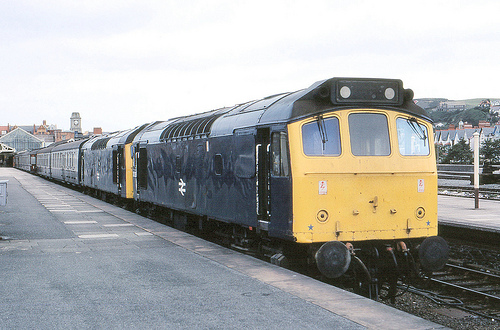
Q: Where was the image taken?
A: It was taken at the train station.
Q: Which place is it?
A: It is a train station.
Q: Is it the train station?
A: Yes, it is the train station.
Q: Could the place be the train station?
A: Yes, it is the train station.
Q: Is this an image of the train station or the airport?
A: It is showing the train station.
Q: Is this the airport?
A: No, it is the train station.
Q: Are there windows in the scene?
A: Yes, there are windows.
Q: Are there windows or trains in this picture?
A: Yes, there are windows.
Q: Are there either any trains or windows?
A: Yes, there are windows.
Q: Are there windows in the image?
A: Yes, there are windows.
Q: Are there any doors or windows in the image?
A: Yes, there are windows.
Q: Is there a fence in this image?
A: No, there are no fences.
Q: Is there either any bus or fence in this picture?
A: No, there are no fences or buses.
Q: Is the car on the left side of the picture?
A: Yes, the car is on the left of the image.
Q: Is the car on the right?
A: No, the car is on the left of the image.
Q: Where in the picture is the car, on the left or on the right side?
A: The car is on the left of the image.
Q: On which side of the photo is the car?
A: The car is on the left of the image.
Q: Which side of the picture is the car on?
A: The car is on the left of the image.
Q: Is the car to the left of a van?
A: No, the car is to the left of a train car.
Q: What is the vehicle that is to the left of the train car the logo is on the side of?
A: The vehicle is a car.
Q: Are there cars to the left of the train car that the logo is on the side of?
A: Yes, there is a car to the left of the train car.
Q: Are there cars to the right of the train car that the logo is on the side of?
A: No, the car is to the left of the train car.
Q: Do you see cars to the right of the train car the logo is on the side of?
A: No, the car is to the left of the train car.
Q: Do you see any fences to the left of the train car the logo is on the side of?
A: No, there is a car to the left of the train car.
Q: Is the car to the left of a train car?
A: Yes, the car is to the left of a train car.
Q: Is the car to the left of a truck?
A: No, the car is to the left of a train car.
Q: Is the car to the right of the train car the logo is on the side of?
A: No, the car is to the left of the train car.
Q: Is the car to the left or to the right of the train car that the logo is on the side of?
A: The car is to the left of the train car.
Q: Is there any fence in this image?
A: No, there are no fences.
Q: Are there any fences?
A: No, there are no fences.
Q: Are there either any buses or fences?
A: No, there are no fences or buses.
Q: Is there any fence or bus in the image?
A: No, there are no fences or buses.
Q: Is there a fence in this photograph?
A: No, there are no fences.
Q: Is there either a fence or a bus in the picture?
A: No, there are no fences or buses.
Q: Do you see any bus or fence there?
A: No, there are no fences or buses.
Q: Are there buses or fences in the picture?
A: No, there are no fences or buses.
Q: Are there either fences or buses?
A: No, there are no fences or buses.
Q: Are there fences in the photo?
A: No, there are no fences.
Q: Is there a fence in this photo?
A: No, there are no fences.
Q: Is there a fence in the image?
A: No, there are no fences.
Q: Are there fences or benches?
A: No, there are no fences or benches.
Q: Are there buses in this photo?
A: No, there are no buses.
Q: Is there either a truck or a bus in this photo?
A: No, there are no buses or trucks.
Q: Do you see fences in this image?
A: No, there are no fences.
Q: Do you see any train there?
A: Yes, there is a train.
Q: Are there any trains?
A: Yes, there is a train.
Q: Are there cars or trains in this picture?
A: Yes, there is a train.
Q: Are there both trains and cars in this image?
A: Yes, there are both a train and a car.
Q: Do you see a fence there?
A: No, there are no fences.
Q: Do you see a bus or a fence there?
A: No, there are no fences or buses.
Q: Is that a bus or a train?
A: That is a train.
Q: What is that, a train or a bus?
A: That is a train.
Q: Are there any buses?
A: No, there are no buses.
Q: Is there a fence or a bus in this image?
A: No, there are no buses or fences.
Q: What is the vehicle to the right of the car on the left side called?
A: The vehicle is a train car.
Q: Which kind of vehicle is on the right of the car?
A: The vehicle is a train car.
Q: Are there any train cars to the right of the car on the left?
A: Yes, there is a train car to the right of the car.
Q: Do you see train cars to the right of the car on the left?
A: Yes, there is a train car to the right of the car.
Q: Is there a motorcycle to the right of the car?
A: No, there is a train car to the right of the car.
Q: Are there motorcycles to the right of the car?
A: No, there is a train car to the right of the car.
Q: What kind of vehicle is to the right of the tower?
A: The vehicle is a train car.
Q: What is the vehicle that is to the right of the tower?
A: The vehicle is a train car.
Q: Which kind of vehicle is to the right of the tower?
A: The vehicle is a train car.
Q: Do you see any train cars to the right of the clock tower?
A: Yes, there is a train car to the right of the tower.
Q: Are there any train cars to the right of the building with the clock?
A: Yes, there is a train car to the right of the tower.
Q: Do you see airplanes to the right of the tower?
A: No, there is a train car to the right of the tower.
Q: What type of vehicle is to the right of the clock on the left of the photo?
A: The vehicle is a train car.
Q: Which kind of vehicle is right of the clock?
A: The vehicle is a train car.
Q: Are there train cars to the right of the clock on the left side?
A: Yes, there is a train car to the right of the clock.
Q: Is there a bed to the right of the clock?
A: No, there is a train car to the right of the clock.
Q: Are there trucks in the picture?
A: No, there are no trucks.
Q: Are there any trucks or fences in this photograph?
A: No, there are no trucks or fences.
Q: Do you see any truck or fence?
A: No, there are no trucks or fences.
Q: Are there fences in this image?
A: No, there are no fences.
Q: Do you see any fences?
A: No, there are no fences.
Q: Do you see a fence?
A: No, there are no fences.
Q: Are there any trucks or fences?
A: No, there are no fences or trucks.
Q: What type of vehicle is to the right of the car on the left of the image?
A: The vehicle is a train car.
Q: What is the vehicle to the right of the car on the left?
A: The vehicle is a train car.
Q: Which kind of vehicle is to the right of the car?
A: The vehicle is a train car.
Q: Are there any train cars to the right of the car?
A: Yes, there is a train car to the right of the car.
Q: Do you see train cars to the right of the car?
A: Yes, there is a train car to the right of the car.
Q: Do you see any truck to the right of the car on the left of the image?
A: No, there is a train car to the right of the car.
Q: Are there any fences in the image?
A: No, there are no fences.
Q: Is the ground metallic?
A: Yes, the ground is metallic.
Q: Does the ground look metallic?
A: Yes, the ground is metallic.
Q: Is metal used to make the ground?
A: Yes, the ground is made of metal.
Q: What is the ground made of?
A: The ground is made of metal.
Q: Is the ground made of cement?
A: No, the ground is made of metal.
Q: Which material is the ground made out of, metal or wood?
A: The ground is made of metal.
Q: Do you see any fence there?
A: No, there are no fences.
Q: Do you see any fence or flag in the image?
A: No, there are no fences or flags.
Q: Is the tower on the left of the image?
A: Yes, the tower is on the left of the image.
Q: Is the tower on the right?
A: No, the tower is on the left of the image.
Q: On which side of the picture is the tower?
A: The tower is on the left of the image.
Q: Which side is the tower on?
A: The tower is on the left of the image.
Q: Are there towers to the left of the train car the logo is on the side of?
A: Yes, there is a tower to the left of the train car.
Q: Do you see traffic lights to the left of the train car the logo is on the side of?
A: No, there is a tower to the left of the train car.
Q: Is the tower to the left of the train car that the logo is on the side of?
A: Yes, the tower is to the left of the train car.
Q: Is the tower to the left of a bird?
A: No, the tower is to the left of the train car.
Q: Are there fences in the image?
A: No, there are no fences.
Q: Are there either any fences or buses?
A: No, there are no fences or buses.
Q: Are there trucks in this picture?
A: No, there are no trucks.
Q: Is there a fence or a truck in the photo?
A: No, there are no trucks or fences.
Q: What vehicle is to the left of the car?
A: The vehicle is a train car.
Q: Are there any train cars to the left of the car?
A: Yes, there is a train car to the left of the car.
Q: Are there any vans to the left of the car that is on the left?
A: No, there is a train car to the left of the car.